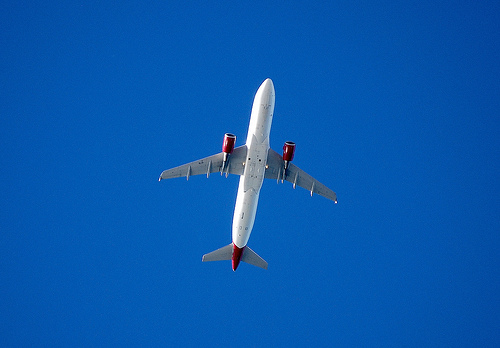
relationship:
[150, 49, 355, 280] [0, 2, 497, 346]
plane in sky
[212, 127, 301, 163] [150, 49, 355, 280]
engines on plane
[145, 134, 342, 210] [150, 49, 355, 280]
wings on plane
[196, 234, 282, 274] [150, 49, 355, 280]
tail on plane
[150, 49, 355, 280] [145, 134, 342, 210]
plane has wings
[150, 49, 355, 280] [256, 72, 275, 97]
plane has nose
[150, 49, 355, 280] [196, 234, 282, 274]
plane has tail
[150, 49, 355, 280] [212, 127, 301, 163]
plane has engines